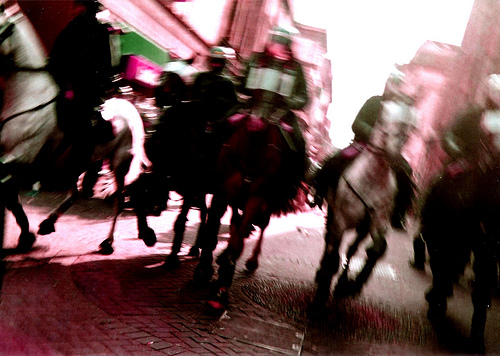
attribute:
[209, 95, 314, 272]
horse — dark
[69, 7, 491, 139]
people — blurry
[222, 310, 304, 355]
square — grate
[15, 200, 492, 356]
streets — bricked, small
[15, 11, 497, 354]
picture — blurry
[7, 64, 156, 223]
horse — white, light color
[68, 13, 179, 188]
store — stand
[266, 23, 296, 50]
helmet — green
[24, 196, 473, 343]
road — red, brick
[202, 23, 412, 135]
riders — three